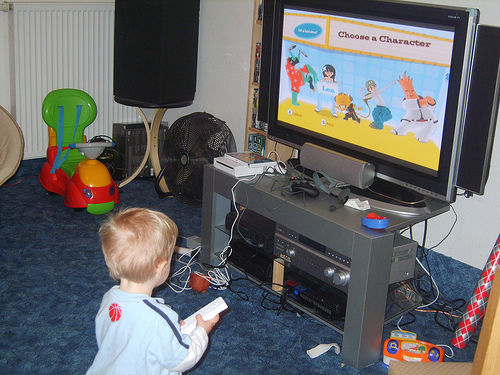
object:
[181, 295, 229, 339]
game controller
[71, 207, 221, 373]
child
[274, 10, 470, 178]
screen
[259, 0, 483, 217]
television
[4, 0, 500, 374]
living room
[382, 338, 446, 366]
videogame